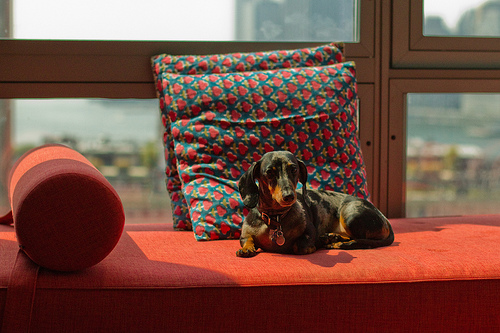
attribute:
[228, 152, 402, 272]
dachshund — little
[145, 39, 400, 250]
pillows — large, throw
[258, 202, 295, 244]
collar — dog's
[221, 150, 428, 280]
dachshund — little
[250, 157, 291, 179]
eyes — dark, gentle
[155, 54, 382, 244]
pillow — green, red, blue, flower-designed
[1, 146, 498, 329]
bed — day, red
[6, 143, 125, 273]
pillow — red, green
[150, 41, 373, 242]
pillow — red, green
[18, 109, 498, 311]
couch — burnt orange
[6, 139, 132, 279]
pillow — circular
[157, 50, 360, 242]
pillows — throw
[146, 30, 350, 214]
pillow — green, red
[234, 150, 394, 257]
dascshund — little 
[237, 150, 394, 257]
dachshund — little, two-tone brown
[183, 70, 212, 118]
pillow — red, green